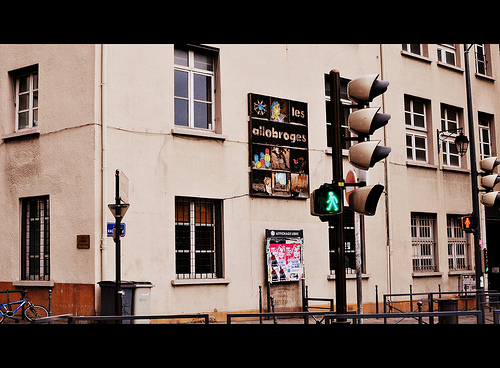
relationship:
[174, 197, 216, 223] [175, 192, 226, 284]
blinds over windows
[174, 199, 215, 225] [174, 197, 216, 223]
blinds in blinds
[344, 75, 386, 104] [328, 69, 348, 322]
light on pole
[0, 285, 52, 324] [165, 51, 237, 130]
bicycle under window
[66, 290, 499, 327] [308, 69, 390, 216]
rail under traffic lights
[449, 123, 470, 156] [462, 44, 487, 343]
light on pole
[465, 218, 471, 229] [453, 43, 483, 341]
light on pole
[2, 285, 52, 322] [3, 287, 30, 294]
bicycle against rail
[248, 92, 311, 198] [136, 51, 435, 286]
colorful sign on building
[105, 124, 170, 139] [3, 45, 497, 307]
wiring on building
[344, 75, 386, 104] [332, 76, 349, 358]
light on pole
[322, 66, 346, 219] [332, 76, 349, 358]
traffic light on pole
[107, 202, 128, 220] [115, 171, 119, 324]
triangular sign on pole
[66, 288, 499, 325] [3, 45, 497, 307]
rails near building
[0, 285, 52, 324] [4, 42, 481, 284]
bicycle under window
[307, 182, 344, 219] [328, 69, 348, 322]
light on pole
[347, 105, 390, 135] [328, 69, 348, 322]
traffic light on pole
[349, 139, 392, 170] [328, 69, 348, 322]
light on pole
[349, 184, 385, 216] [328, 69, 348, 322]
light on pole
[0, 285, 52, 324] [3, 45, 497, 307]
bicycle leaning against wall of building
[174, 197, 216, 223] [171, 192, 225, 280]
blinds on window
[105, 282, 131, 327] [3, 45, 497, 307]
trash bin next to building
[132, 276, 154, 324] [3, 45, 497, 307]
trash bin next to building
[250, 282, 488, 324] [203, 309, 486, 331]
poles on sidewalk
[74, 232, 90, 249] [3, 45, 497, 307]
plaque on side of building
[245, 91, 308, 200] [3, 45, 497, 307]
colorful sign on side of building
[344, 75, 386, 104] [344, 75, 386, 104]
light on light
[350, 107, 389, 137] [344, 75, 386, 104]
light on light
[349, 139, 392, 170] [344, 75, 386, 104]
light on light